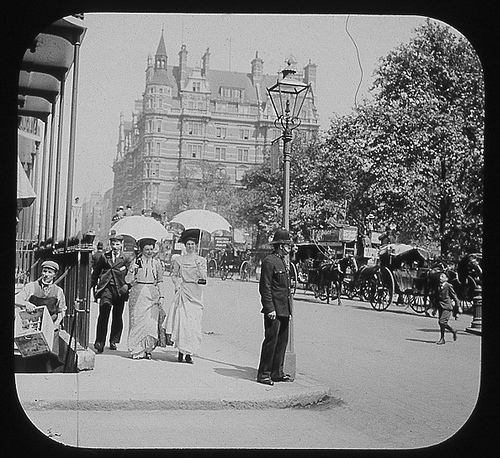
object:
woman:
[125, 240, 166, 361]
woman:
[170, 234, 206, 366]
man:
[255, 230, 296, 386]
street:
[210, 291, 483, 427]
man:
[15, 260, 67, 373]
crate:
[15, 306, 55, 358]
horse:
[318, 254, 357, 307]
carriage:
[290, 243, 315, 299]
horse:
[424, 255, 482, 322]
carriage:
[366, 242, 483, 314]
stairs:
[15, 248, 93, 374]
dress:
[174, 253, 205, 352]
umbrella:
[106, 212, 173, 283]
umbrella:
[167, 203, 237, 270]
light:
[268, 64, 311, 136]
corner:
[247, 377, 354, 426]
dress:
[129, 257, 172, 356]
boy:
[431, 270, 463, 347]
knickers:
[432, 311, 459, 331]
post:
[282, 134, 291, 226]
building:
[111, 21, 320, 209]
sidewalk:
[5, 338, 322, 415]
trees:
[296, 17, 487, 253]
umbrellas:
[109, 208, 235, 243]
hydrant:
[464, 280, 484, 335]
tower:
[142, 23, 170, 213]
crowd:
[88, 208, 234, 368]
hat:
[270, 228, 296, 244]